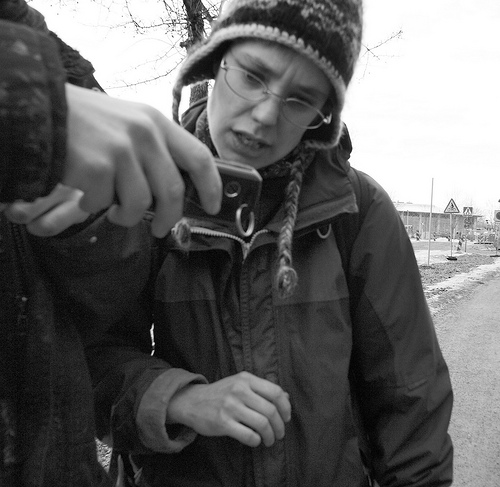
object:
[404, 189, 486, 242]
building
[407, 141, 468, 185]
background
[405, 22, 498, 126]
sky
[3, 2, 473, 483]
people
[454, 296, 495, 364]
road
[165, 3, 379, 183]
woman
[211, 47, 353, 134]
down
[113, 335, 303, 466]
arm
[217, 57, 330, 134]
glasses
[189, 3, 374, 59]
warm hat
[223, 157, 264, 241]
cell phone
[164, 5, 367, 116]
person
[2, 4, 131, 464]
person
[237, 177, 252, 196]
operate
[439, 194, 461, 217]
sign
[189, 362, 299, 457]
hand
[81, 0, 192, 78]
tree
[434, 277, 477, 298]
parking strip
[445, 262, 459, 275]
grass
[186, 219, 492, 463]
coat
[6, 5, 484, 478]
picture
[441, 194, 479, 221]
signs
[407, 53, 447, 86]
day time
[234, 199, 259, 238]
ring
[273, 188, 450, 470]
winter jacket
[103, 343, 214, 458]
jacket sleeve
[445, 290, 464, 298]
dirt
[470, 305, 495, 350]
ground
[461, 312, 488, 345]
street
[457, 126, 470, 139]
distance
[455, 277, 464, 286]
snow